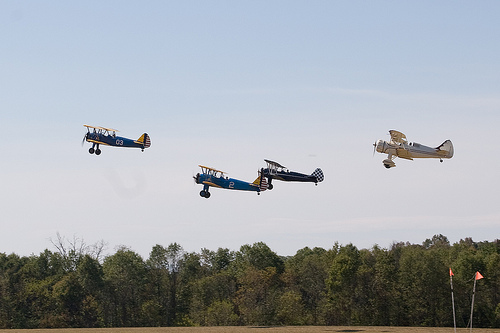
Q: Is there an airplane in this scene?
A: Yes, there is an airplane.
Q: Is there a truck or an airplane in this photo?
A: Yes, there is an airplane.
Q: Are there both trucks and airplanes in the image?
A: No, there is an airplane but no trucks.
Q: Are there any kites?
A: No, there are no kites.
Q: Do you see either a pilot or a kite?
A: No, there are no kites or pilots.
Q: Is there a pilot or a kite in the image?
A: No, there are no kites or pilots.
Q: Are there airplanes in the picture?
A: Yes, there is an airplane.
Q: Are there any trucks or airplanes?
A: Yes, there is an airplane.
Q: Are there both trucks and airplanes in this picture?
A: No, there is an airplane but no trucks.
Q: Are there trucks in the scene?
A: No, there are no trucks.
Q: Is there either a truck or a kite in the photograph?
A: No, there are no trucks or kites.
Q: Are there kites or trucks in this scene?
A: No, there are no trucks or kites.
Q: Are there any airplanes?
A: Yes, there are airplanes.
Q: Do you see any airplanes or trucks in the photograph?
A: Yes, there are airplanes.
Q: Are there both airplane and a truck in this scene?
A: No, there are airplanes but no trucks.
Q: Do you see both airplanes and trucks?
A: No, there are airplanes but no trucks.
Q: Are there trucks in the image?
A: No, there are no trucks.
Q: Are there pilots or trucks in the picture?
A: No, there are no trucks or pilots.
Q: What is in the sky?
A: The airplanes are in the sky.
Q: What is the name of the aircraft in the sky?
A: The aircraft is airplanes.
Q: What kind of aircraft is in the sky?
A: The aircraft is airplanes.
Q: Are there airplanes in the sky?
A: Yes, there are airplanes in the sky.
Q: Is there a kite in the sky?
A: No, there are airplanes in the sky.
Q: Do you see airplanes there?
A: Yes, there is an airplane.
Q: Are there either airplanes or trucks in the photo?
A: Yes, there is an airplane.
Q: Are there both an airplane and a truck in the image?
A: No, there is an airplane but no trucks.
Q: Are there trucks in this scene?
A: No, there are no trucks.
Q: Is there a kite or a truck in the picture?
A: No, there are no trucks or kites.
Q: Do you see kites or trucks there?
A: No, there are no trucks or kites.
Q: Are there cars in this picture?
A: No, there are no cars.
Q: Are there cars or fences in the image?
A: No, there are no cars or fences.